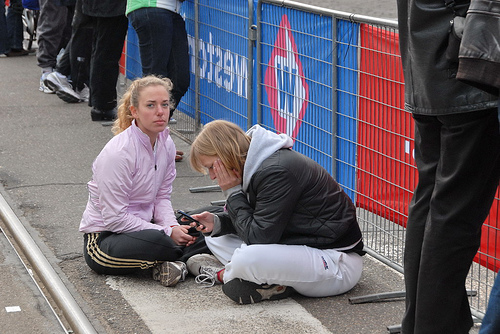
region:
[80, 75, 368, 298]
two women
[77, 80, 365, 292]
two women sitting on the ground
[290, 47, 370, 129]
a metal fence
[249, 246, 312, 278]
the women is wearing white pants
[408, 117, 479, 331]
the person is wearing black pants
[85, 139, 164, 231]
a jacket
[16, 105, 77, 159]
the ground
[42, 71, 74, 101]
a persons shoe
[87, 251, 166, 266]
stripes on the pants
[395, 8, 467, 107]
a leather jacket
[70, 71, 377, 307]
two women sitting on the ground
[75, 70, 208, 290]
woman with pink jacket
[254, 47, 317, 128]
logo on the banner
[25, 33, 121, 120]
legs of the people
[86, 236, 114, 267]
yellow stripes on the pants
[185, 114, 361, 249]
woman wearing a black jacket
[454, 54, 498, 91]
sleeve of the black jacket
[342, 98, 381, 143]
fence in front of the banner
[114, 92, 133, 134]
pony tail in the hair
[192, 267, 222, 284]
laces on the sneaker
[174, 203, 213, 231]
the young lady on the right is checking her phone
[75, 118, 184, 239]
the young lady on the left wears a pink top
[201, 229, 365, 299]
the lady on the right wears white pants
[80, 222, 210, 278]
the lady on the left wears sweat pants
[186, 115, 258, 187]
the lady on the right has blond hair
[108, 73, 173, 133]
the lady on the left wears her hair in a pony tail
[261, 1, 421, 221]
the wall behind the ladies is red and blue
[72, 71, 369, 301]
two young ladies sit on the asphalt to wait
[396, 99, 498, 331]
a gentleman near the ladies wears black trousers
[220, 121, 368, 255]
the lady on the right wears a black ski jacket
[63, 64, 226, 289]
lady sitting on the ground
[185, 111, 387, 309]
lady sitting on the ground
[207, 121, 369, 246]
black jacket with hood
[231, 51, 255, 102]
white letter on a sign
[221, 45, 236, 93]
white letter on a sign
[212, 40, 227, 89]
white letter on a sign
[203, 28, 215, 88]
white letter on a sign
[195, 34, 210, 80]
white letter on a sign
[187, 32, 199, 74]
white letter on a sign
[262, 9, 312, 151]
logo on a sign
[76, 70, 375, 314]
Two women are sitting on the ground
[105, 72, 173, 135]
Blonde hair in a ponytail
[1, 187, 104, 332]
The curb of a sidewalk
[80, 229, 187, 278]
White stripes on black pants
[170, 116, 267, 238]
Woman looking at her cell phone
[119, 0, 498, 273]
A blue and red sign on fence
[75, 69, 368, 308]
Two women are sitting cross legged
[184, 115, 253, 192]
Blonde hair on woman's head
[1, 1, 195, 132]
People standing in front of a fence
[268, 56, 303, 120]
Letter "W" on a sign